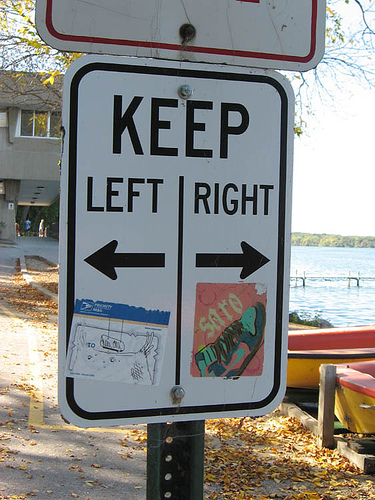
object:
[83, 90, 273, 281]
sign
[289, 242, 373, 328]
water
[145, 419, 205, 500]
pole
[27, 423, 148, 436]
lines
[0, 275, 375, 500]
ground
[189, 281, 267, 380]
sticker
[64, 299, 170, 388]
sticker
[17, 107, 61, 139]
window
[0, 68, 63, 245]
building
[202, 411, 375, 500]
leaves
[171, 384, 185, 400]
bolt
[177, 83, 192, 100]
bolt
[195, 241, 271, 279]
arrow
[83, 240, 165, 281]
arrow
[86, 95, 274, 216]
letters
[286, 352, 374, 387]
paint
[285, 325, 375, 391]
boat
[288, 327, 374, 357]
paint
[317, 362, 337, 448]
pole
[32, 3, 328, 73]
sign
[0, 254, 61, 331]
leaves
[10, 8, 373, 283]
background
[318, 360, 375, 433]
boats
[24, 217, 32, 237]
people